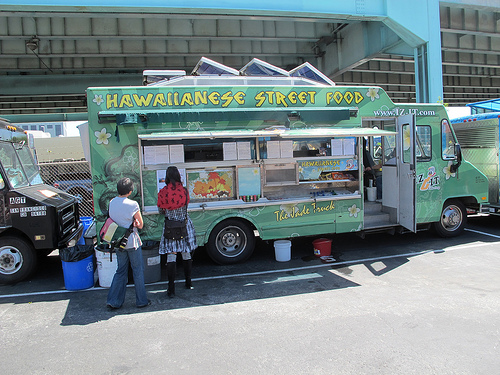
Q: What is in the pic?
A: Food truck.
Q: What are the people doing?
A: Ordering.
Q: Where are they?
A: Outside on sidewalk.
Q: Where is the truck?
A: Street.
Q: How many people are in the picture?
A: Two.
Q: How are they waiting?
A: In line.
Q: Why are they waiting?
A: For food.